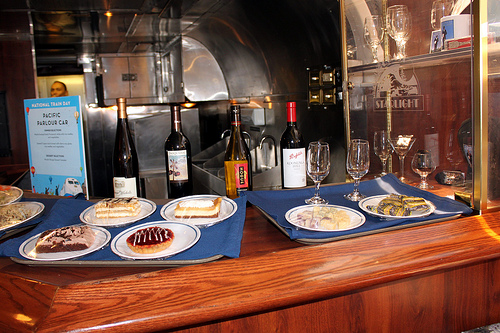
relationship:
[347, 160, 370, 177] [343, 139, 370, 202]
liquid in glass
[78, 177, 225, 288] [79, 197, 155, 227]
cake on plate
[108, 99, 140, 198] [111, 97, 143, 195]
wine in bottle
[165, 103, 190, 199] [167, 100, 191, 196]
wine in bottle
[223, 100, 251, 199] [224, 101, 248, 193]
wine in bottle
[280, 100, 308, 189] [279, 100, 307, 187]
wine in bottle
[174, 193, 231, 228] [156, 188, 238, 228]
dessert on plate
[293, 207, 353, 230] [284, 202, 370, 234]
food on plate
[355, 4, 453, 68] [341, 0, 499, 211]
glasses in case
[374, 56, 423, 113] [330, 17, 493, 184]
logo on glass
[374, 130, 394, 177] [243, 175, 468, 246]
glass on tray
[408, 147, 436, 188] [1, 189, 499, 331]
glass on bar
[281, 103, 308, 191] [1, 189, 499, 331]
bottle on bar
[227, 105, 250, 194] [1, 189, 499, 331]
bottle on bar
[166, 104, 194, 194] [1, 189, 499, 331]
bottle on bar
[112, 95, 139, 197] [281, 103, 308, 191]
bottle on bottle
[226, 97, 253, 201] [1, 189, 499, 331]
wine bottle on bar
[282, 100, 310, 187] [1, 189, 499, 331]
wine bottle on bar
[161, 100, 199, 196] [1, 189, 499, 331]
wine bottle on bar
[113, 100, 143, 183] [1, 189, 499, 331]
wine bottle on bar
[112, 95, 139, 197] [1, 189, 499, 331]
bottle on bar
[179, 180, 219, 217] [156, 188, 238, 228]
pastry on plate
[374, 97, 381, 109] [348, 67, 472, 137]
letter on glass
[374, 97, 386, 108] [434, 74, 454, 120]
letter on glass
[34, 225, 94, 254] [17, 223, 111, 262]
food on plate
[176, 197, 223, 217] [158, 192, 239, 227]
food on plate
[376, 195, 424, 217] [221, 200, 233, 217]
food on plate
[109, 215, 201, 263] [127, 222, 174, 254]
plate has food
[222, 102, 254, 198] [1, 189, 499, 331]
bottle in bar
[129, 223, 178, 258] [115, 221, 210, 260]
pastry on plate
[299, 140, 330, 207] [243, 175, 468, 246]
glass on tray